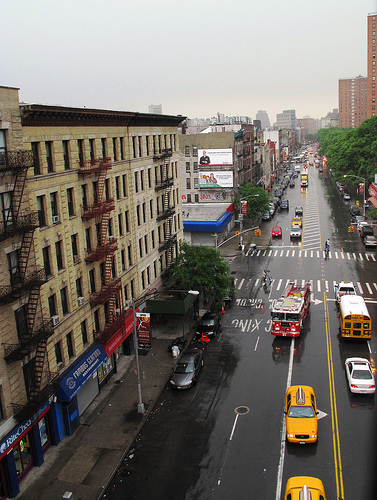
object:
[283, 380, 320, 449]
cab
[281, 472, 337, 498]
cab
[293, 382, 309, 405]
sign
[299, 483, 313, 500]
sign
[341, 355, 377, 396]
car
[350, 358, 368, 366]
sun roof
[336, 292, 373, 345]
school bus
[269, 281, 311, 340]
fire truck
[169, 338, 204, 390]
car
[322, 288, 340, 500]
yellow lines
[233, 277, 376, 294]
cross walk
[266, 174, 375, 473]
street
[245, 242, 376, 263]
cross walk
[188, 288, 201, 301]
light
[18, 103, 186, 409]
apartments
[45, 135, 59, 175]
window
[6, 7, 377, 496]
photo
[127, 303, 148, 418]
pole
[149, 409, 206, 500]
tarmac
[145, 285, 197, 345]
canopy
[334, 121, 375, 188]
tree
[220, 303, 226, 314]
traffic cone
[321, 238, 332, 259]
person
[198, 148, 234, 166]
billboard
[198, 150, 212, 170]
people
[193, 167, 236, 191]
billboard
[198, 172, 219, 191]
people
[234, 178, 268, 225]
trees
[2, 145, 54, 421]
fire escape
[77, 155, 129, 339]
fire escape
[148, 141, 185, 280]
fire escape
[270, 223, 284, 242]
car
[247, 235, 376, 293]
intersection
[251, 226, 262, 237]
traffic light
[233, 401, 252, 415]
manhole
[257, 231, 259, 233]
red